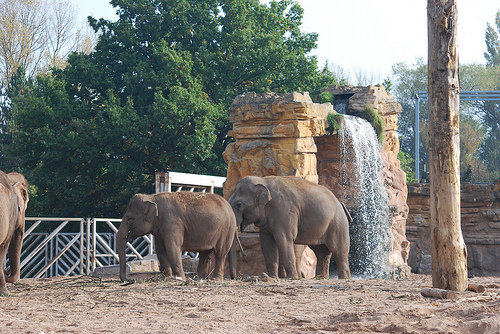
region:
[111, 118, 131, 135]
part of a branch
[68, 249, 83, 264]
part of a fence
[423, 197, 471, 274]
part of a pole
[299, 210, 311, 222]
body of an elephant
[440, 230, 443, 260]
part of a pole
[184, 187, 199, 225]
back of an elephant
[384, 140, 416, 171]
part of a wall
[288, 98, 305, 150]
edge of a wall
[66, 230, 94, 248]
edge of a fence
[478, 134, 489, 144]
part of a tree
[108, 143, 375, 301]
elephants are standing still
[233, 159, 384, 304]
elephant is behind smaller elephant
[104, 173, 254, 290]
the elephant is a baby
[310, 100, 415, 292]
water coming out of structure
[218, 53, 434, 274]
the structure is brown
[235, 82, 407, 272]
structure made of rock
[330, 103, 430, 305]
water is hitting the ground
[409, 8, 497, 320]
tree trunk near elephants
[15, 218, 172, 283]
the fencing is silver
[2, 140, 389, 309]
elephants are in containment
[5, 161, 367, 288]
three elephants in enclouse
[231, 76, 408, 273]
rock water fall in elephant enclosure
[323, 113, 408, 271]
water spilling from waterfall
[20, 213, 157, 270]
white doors of enclosure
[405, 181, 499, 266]
stone wall behind bare tree trunk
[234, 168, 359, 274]
elephant standing next to waterfall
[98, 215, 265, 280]
trunks of two elephants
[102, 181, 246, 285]
elephant in the middle of three elephants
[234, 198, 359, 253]
tails of two elephants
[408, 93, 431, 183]
gray pole on top of stone wall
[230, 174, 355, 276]
large grey colored elephant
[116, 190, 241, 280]
large grey colored elephant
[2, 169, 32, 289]
large grey colored elephant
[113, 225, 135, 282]
long grey elephant trunk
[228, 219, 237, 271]
long grey elephant trunk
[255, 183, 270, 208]
grey colored elephant ear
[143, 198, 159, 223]
grey colored elephant ear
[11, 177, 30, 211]
grey colored elephant ear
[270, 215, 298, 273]
long grey elephant leg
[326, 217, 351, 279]
long grey elephant leg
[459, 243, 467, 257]
part of a pole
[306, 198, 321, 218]
part of an elephant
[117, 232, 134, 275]
trunk of an elephant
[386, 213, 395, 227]
part of a wall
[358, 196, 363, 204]
part of water ball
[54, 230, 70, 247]
part of a post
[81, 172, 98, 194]
part of a bush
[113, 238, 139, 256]
part of an ear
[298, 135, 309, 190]
edge of a wall